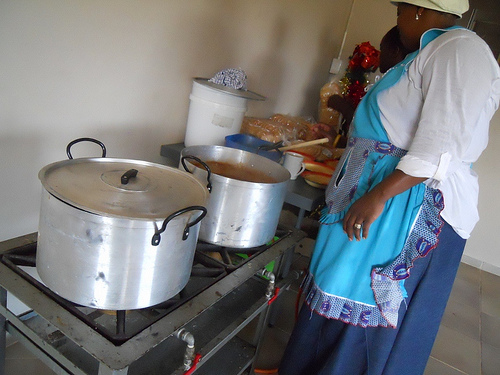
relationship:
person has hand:
[282, 2, 499, 374] [339, 193, 385, 240]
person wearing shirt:
[282, 2, 499, 374] [379, 28, 499, 242]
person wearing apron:
[282, 2, 499, 374] [301, 25, 442, 327]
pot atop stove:
[36, 155, 211, 307] [0, 213, 305, 373]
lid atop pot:
[41, 157, 207, 218] [36, 155, 211, 307]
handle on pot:
[154, 207, 209, 248] [36, 155, 211, 307]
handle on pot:
[66, 136, 107, 161] [36, 155, 211, 307]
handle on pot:
[180, 153, 213, 191] [36, 155, 211, 307]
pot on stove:
[36, 155, 211, 307] [0, 213, 305, 373]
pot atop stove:
[176, 147, 297, 250] [0, 213, 305, 373]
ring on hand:
[354, 221, 362, 231] [339, 193, 385, 240]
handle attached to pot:
[154, 207, 209, 248] [36, 155, 211, 307]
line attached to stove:
[176, 330, 202, 374] [0, 213, 305, 373]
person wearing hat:
[282, 2, 499, 374] [403, 0, 471, 17]